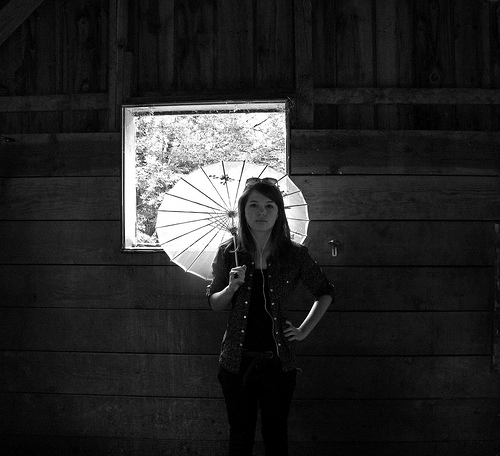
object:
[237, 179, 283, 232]
head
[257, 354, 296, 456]
leg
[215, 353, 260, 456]
leg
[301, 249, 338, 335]
arm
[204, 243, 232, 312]
arm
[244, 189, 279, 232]
face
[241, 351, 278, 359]
belt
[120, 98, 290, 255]
window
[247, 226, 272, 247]
neck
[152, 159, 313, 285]
parasol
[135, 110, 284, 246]
trees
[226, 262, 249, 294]
hand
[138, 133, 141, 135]
leaves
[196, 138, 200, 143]
leaves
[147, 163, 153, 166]
leaves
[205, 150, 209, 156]
leaves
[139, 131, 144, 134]
leaves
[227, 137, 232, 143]
leaves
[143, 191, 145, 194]
leaves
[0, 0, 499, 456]
building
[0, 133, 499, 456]
wall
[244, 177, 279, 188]
sunglasses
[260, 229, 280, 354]
wire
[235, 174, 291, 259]
hair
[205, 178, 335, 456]
girl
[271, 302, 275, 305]
button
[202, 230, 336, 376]
jacket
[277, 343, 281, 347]
button